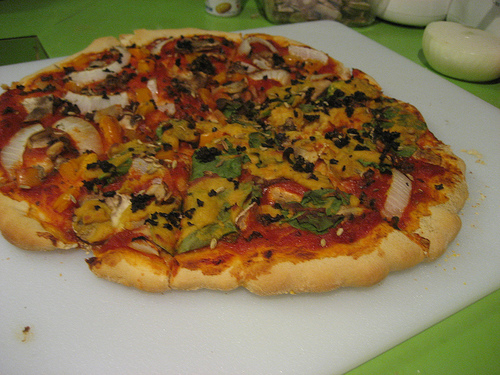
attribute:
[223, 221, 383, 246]
sauce — red, pizza sauce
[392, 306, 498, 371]
surface — green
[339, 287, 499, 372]
counter top — green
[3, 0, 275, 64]
counter top — green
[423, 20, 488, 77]
onion — cut, halved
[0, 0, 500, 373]
table cloth — green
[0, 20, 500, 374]
cutting board — white, plastic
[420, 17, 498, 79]
onion — white 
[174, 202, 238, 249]
pepper — green, yellow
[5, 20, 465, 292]
pizza — cut, cheeseless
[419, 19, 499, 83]
onion — cut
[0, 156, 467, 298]
crust — thin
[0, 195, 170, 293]
crust — broken